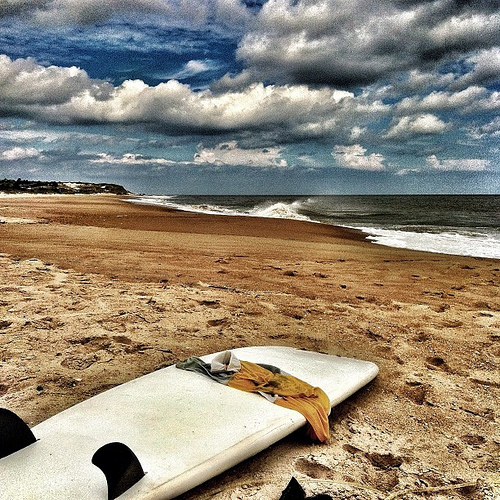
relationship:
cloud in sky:
[42, 70, 372, 157] [2, 2, 500, 196]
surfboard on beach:
[2, 343, 391, 500] [0, 193, 495, 495]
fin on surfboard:
[84, 435, 167, 499] [2, 343, 391, 500]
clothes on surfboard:
[172, 344, 339, 438] [2, 343, 391, 500]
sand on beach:
[39, 251, 335, 297] [0, 193, 495, 495]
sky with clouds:
[2, 2, 500, 196] [231, 2, 496, 150]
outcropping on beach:
[5, 176, 128, 199] [0, 193, 495, 495]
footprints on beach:
[269, 258, 472, 328] [0, 193, 495, 495]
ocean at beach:
[134, 191, 497, 259] [0, 193, 495, 495]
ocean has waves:
[134, 191, 497, 259] [143, 191, 332, 228]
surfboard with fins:
[2, 343, 391, 500] [2, 406, 150, 499]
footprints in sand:
[269, 258, 472, 328] [39, 251, 335, 297]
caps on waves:
[260, 198, 303, 211] [143, 191, 332, 228]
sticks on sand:
[126, 343, 173, 358] [39, 251, 335, 297]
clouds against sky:
[231, 2, 496, 150] [2, 2, 500, 196]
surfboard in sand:
[2, 343, 391, 500] [39, 251, 335, 297]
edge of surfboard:
[341, 362, 383, 397] [2, 343, 391, 500]